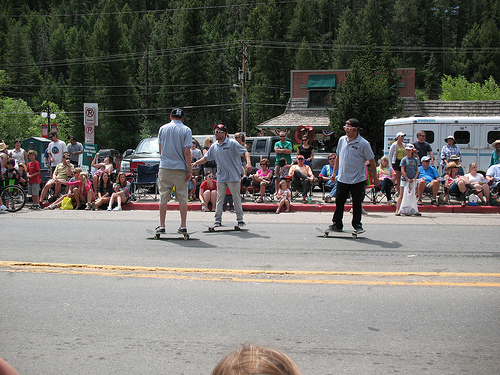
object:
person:
[153, 107, 194, 234]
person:
[190, 124, 252, 227]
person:
[106, 172, 133, 211]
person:
[294, 133, 316, 165]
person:
[327, 118, 382, 235]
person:
[287, 154, 315, 204]